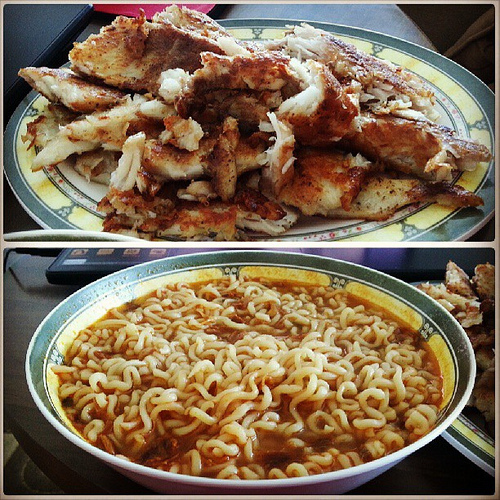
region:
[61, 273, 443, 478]
Noodles in the bowl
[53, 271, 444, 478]
Sauce on the noodles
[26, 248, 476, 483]
A bowl full of food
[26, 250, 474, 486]
The bowl is circular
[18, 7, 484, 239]
Meat on the plate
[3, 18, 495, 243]
A plate beneath the meat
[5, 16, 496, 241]
The plate is circular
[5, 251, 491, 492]
A table beneath the food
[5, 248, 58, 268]
A cord plugged into a device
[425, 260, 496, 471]
A plate of meat next to the noodles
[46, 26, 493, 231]
Meat on a plate.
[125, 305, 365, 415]
Noodles in a bowl.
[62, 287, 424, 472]
The noodles are in broth.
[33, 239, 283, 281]
Remote on the table.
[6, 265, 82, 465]
The table is wooden.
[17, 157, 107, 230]
Design on the plate.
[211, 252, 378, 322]
Design on the bowl.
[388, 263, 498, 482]
Plate next to the bowl.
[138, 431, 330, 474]
Meat in the soup.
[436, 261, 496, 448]
The meat is cooked.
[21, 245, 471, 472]
ramen noodles in a bowl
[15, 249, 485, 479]
bowl with green edge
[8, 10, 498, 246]
plate with green edge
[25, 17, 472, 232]
meat on green and yellow plate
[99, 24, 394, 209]
barbecue sauce on meat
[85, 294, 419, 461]
noodles in green and yellow bowl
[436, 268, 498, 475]
plate next to bowl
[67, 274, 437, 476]
red liquid noodles are in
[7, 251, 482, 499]
table bowl is sitting on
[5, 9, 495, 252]
table plate is on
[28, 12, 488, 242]
a plate of food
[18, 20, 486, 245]
a yellow and white plate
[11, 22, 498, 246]
a large plate of meat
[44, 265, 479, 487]
a yellow and green bowl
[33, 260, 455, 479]
a bowl of noodles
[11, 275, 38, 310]
the table under the bowl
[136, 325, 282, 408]
the noodles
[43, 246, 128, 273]
a remote on the table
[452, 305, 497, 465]
the edge of a plate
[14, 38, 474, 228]
a pile of meat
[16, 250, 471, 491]
bowl of ramen noodles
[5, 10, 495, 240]
a plate full of fish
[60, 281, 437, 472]
noodles in sauce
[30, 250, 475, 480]
bowl with green and yellow pattern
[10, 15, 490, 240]
plate with green and yellow pattern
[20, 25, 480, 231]
pile of fish on a plate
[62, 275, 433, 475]
curly Ramen noodles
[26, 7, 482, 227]
grilled fish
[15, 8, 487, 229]
food on a green and yellow plate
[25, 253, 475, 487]
a bowl of noodle soup